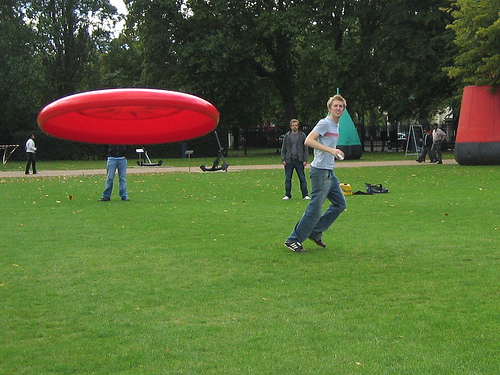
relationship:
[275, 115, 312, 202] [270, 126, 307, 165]
man wears jacket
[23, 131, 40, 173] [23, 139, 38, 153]
person wears shirt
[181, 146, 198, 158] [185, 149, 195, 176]
metal plaque on pole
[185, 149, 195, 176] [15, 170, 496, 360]
pole in ground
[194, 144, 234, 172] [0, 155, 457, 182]
anchor decor on sidewalk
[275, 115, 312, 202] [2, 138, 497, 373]
man in field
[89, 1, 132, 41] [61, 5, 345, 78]
light in trees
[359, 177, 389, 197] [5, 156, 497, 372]
backpack in grass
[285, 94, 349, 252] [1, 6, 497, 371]
boy in park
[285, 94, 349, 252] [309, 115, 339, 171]
boy in shirt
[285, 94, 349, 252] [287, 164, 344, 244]
boy in jeans